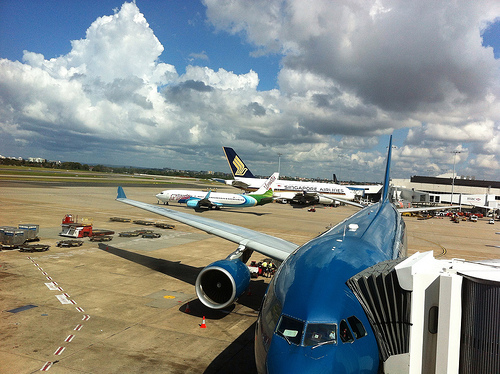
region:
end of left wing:
[108, 185, 133, 201]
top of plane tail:
[371, 128, 407, 148]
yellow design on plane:
[231, 155, 245, 172]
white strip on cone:
[201, 321, 207, 323]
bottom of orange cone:
[199, 325, 208, 328]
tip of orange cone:
[200, 312, 206, 319]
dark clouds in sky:
[358, 72, 438, 105]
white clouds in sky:
[118, 69, 186, 104]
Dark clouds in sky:
[381, 76, 416, 101]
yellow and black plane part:
[216, 143, 260, 178]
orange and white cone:
[196, 318, 210, 328]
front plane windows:
[273, 320, 348, 348]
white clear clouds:
[60, 23, 132, 74]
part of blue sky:
[7, 32, 57, 49]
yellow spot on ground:
[158, 288, 178, 303]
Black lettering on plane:
[287, 180, 334, 190]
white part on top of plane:
[338, 213, 361, 234]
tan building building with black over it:
[395, 178, 475, 190]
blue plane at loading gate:
[162, 202, 386, 369]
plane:
[161, 175, 286, 213]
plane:
[227, 146, 354, 204]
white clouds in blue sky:
[52, 49, 129, 91]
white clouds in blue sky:
[280, 49, 331, 91]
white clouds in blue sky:
[365, 53, 422, 64]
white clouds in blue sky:
[178, 25, 240, 89]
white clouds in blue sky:
[10, 25, 95, 90]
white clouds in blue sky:
[67, 75, 159, 160]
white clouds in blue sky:
[131, 22, 183, 76]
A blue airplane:
[110, 164, 435, 366]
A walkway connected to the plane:
[357, 253, 498, 361]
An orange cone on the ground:
[195, 307, 211, 332]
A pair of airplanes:
[132, 134, 364, 206]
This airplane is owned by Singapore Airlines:
[220, 147, 356, 207]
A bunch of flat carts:
[11, 210, 177, 250]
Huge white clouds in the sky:
[21, 33, 498, 145]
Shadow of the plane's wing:
[102, 241, 194, 284]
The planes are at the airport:
[114, 145, 469, 359]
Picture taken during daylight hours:
[16, 28, 474, 206]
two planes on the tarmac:
[141, 138, 363, 223]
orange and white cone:
[196, 313, 210, 333]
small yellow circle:
[161, 289, 173, 302]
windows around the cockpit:
[261, 307, 367, 356]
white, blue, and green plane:
[149, 168, 284, 216]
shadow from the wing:
[97, 238, 267, 326]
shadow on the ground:
[221, 206, 276, 221]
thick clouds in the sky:
[0, 0, 499, 192]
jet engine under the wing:
[106, 177, 294, 323]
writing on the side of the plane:
[281, 180, 348, 195]